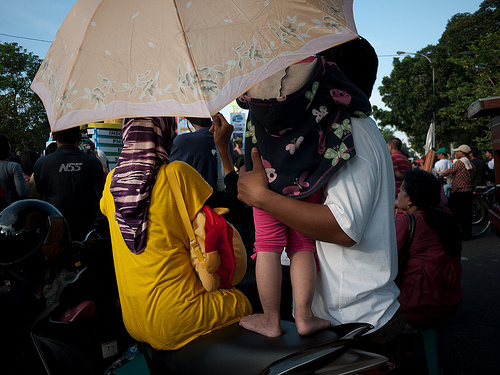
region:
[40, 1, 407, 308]
people under an umbrella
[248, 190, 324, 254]
a person in pink pants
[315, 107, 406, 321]
a person wearing a white tee shirt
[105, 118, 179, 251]
a woman wearing a cloth head scarf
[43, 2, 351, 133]
an open umbrella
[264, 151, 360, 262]
a person's left arm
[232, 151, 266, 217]
a person's left hand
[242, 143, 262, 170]
the thumb of a person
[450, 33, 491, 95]
green leaves on a tree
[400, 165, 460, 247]
a woman with long hair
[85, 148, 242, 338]
Person wearing a yellow shirt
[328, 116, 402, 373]
person wearing a white tee shirt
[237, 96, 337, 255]
man holding a child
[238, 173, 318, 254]
child wearing pink pants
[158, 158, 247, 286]
woman holding a back pack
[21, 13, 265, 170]
person holding a umbrella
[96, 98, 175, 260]
woman wearing a scarf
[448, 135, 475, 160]
person wearing a hat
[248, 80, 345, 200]
child wearing a black hoodie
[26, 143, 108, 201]
man wearing a black shirt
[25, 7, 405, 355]
adults and child under an open umbrella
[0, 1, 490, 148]
blue sky in back of tan umbrella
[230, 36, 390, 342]
adult's arm around back of child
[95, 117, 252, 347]
woman in scarf and yellow dress seated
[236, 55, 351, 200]
hooded jacket with colorful butterflies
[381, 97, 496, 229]
people turned in the same direction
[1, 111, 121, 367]
dark bike in back of standing people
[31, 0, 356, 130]
white border with green and white leaves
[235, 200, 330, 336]
pink shorts over bare legs with feet pointed out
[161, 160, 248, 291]
strap of yellow bag with red fabric over shoulder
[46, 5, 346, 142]
a peach umbrella with white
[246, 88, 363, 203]
a black jacket with butterflies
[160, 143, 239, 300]
a yellow strap of a purse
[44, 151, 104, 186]
White letters on back of shirt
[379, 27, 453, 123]
a light pole sticking out of trees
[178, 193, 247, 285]
an arm of a stuffed animal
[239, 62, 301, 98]
white inside the hood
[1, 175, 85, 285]
a black motorcycle helmet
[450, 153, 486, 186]
a white towel on shoulder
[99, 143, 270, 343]
a yellow dress on woman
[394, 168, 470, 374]
a woman sitting in her red dress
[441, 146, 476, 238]
a person is wearing a brown color cap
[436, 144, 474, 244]
the person has white napkin in his shoulder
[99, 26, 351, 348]
a woman wearing yellow dress by the side of the kid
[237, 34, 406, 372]
the guy in white t-shirt is holding a kid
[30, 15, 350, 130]
an umbrella with designs of leaves in its border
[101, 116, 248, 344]
the woman is wearing a bag in her shoulder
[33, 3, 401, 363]
a family under the umbrella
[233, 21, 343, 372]
a kid is standing on a vehicle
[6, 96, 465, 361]
a group of people are sitting